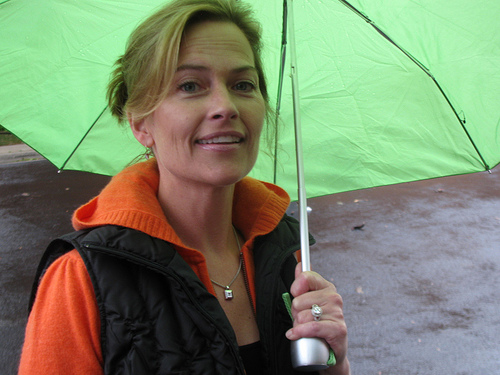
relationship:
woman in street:
[11, 0, 354, 375] [2, 164, 499, 375]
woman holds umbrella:
[11, 0, 354, 375] [0, 0, 497, 205]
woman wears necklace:
[11, 0, 354, 375] [181, 219, 255, 307]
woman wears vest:
[11, 0, 354, 375] [30, 209, 324, 374]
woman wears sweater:
[11, 0, 354, 375] [20, 165, 292, 373]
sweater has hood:
[20, 165, 292, 373] [69, 159, 294, 246]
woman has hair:
[11, 0, 354, 375] [105, 5, 282, 144]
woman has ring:
[11, 0, 354, 375] [311, 305, 323, 320]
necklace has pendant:
[181, 219, 255, 307] [223, 288, 232, 300]